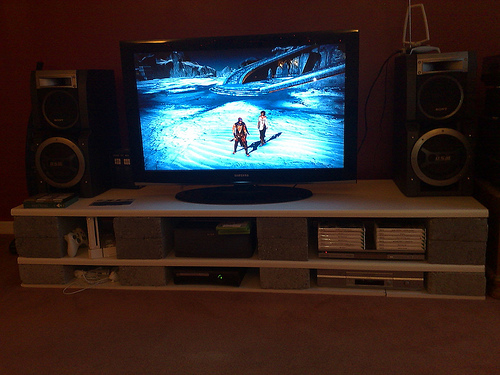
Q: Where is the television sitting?
A: On a shelf.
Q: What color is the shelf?
A: White.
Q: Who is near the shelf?
A: No one.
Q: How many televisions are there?
A: One.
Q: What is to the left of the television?
A: A speaker.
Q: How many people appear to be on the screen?
A: Two.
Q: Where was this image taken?
A: In a living room.